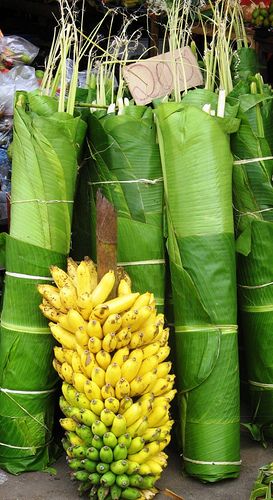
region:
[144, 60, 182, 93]
this is a writing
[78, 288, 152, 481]
this is a banana trunk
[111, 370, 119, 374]
the banana is yellow in color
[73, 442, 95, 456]
the banana is green in color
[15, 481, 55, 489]
this is the ground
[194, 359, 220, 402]
the leaf is green in color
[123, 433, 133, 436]
this is the tip of the banana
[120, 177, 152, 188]
this is a rope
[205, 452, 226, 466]
the rope is white in color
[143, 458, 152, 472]
part of a banana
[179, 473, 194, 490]
part of a floor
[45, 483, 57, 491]
part of a floor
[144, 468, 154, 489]
part of a banana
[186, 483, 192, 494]
part of a floor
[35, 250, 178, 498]
large stalk of bannana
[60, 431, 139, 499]
section of bannan not ripe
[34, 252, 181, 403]
section of fully ripe bananna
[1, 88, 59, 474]
fresh bananna leaves rapped up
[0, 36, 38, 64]
plastic with lime inside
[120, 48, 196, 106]
sign with price of banana leaves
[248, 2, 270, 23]
lot of lime in the backround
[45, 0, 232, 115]
shuts from banana leave tree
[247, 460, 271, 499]
leaves laying on the ground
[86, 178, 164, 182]
string keeping banna leaves together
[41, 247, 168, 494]
banana bunches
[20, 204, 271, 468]
rolled banana leaf with bunches of banana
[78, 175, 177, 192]
rolled banana leaf tied with thread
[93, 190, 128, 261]
stem of banana bunches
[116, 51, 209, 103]
price card kept in the banana leaf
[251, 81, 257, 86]
stem in the banana leaf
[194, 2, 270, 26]
vegetables in the wooden table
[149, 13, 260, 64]
wooden table near the banana leafs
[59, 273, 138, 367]
yellow color bananas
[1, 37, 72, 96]
some covers near the banana leaves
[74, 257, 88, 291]
a ripe yellow banana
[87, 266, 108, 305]
a ripe yellow banana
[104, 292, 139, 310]
a ripe yellow banana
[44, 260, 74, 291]
a ripe yellow banana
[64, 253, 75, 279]
a ripe yellow banana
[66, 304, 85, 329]
a ripe yellow banana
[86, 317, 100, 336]
a ripe yellow banana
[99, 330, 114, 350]
a ripe yellow banana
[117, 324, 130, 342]
a ripe yellow banana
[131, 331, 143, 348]
a ripe yellow banana